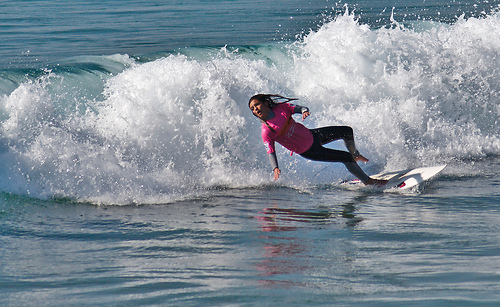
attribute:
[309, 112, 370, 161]
leg — woman's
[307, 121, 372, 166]
pants — black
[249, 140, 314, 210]
arm — woman's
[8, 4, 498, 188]
wave — large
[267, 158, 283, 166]
band — gray